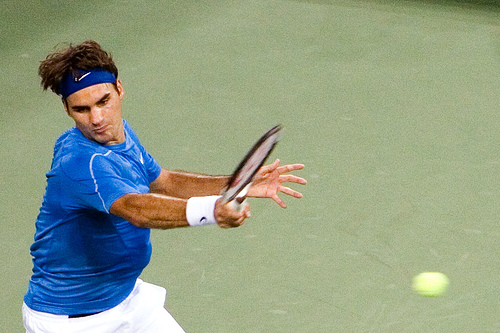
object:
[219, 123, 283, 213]
tennis racket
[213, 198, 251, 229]
hand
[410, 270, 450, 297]
tennis ball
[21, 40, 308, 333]
man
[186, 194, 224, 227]
wrist guard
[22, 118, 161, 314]
t-shirt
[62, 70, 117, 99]
headband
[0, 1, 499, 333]
tennis court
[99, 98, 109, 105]
left eye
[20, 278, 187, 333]
shorts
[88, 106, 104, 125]
nose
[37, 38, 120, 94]
hair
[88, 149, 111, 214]
stripe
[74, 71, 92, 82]
swoosh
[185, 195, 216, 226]
right wrist